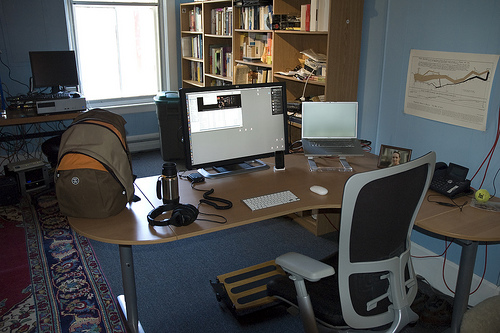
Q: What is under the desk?
A: A foot rest.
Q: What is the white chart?
A: On the wall.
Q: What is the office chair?
A: Black and grey.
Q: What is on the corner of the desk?
A: A brown and orange backpack.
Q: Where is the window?
A: In the back of the room.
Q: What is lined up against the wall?
A: Bookshelves.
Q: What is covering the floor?
A: Carpet and throw rug.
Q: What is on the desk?
A: Two computers.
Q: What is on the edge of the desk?
A: Backpack.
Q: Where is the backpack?
A: On the desk.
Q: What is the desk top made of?
A: Wood.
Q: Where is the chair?
A: Under the desk.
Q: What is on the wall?
A: Chart.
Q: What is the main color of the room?
A: Blue.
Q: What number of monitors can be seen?
A: 3.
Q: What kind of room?
A: Office.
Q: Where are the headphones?
A: On the desk.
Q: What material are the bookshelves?
A: Wood.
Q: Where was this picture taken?
A: An office.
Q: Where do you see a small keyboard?
A: On the desk.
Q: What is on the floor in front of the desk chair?
A: A footrest.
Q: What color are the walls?
A: Blue.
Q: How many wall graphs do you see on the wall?
A: One.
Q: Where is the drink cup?
A: On the desk.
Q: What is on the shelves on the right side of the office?
A: Books.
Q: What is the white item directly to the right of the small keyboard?
A: A mouse.